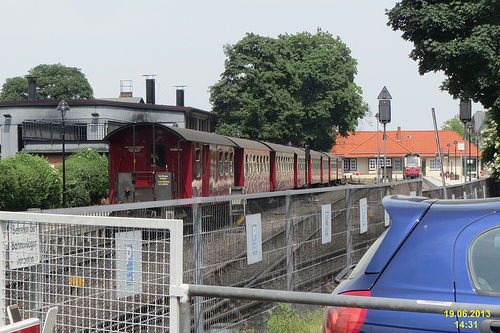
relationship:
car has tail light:
[318, 193, 498, 332] [322, 291, 369, 330]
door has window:
[452, 209, 498, 332] [466, 227, 499, 295]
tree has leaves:
[210, 0, 499, 180] [280, 86, 312, 103]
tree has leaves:
[386, 3, 497, 102] [438, 22, 468, 42]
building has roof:
[330, 131, 480, 178] [331, 131, 482, 156]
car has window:
[102, 122, 346, 205] [194, 149, 338, 179]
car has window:
[102, 122, 346, 205] [259, 155, 266, 172]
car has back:
[102, 122, 346, 205] [106, 125, 190, 224]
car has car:
[102, 122, 346, 205] [231, 136, 274, 196]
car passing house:
[102, 122, 346, 205] [0, 99, 215, 170]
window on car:
[194, 149, 338, 179] [102, 122, 346, 205]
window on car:
[259, 155, 266, 172] [102, 122, 346, 205]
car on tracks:
[231, 136, 274, 196] [28, 223, 322, 294]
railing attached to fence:
[187, 285, 500, 319] [0, 210, 186, 333]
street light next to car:
[56, 97, 73, 206] [102, 122, 346, 205]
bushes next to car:
[0, 150, 106, 205] [102, 122, 346, 205]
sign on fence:
[118, 233, 141, 298] [0, 210, 186, 333]